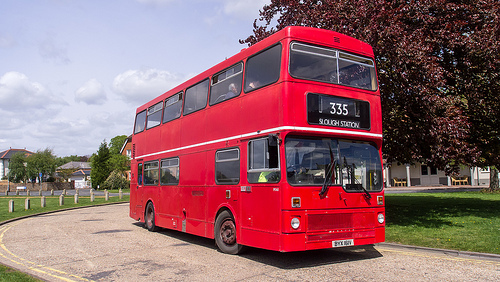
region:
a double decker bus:
[107, 21, 401, 266]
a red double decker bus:
[99, 21, 411, 261]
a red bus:
[106, 8, 412, 253]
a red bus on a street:
[102, 18, 397, 280]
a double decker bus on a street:
[84, 8, 412, 278]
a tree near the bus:
[240, 2, 499, 174]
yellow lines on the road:
[0, 236, 73, 280]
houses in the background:
[2, 133, 144, 193]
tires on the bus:
[140, 193, 250, 253]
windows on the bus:
[122, 28, 288, 130]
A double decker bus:
[125, 23, 389, 263]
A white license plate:
[328, 235, 356, 251]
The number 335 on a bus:
[322, 95, 353, 118]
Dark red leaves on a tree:
[234, 0, 497, 174]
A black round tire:
[211, 203, 250, 258]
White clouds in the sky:
[1, 1, 280, 156]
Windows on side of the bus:
[131, 39, 283, 133]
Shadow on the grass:
[383, 189, 498, 234]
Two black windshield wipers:
[317, 155, 375, 205]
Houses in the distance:
[1, 144, 99, 191]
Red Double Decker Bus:
[113, 43, 395, 258]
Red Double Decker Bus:
[211, 99, 391, 251]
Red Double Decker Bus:
[131, 103, 233, 233]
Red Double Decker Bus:
[250, 160, 347, 252]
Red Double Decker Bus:
[251, 18, 402, 264]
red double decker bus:
[130, 22, 388, 260]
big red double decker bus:
[130, 19, 391, 251]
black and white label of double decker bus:
[305, 92, 370, 133]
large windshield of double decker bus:
[290, 132, 380, 196]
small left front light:
[374, 208, 385, 228]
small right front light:
[282, 213, 299, 228]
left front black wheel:
[210, 206, 245, 248]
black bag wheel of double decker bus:
[135, 199, 155, 233]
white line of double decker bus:
[131, 125, 388, 165]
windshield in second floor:
[285, 36, 383, 91]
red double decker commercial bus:
[127, 26, 387, 256]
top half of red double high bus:
[127, 27, 382, 159]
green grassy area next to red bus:
[388, 188, 495, 248]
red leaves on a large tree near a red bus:
[238, 2, 490, 167]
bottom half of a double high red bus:
[128, 125, 386, 255]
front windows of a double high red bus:
[279, 128, 389, 192]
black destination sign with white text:
[304, 87, 370, 132]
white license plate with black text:
[329, 237, 354, 249]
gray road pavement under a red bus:
[0, 197, 497, 277]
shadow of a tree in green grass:
[385, 192, 497, 225]